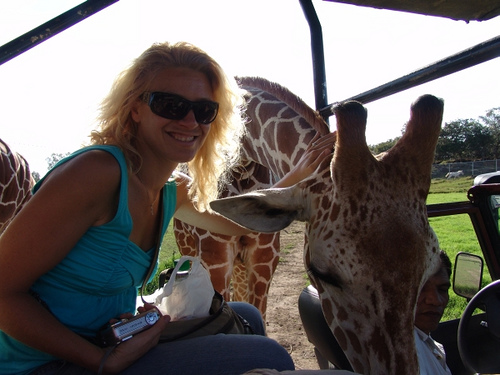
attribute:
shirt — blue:
[0, 137, 183, 366]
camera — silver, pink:
[101, 307, 159, 349]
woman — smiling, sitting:
[1, 38, 351, 375]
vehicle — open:
[0, 1, 499, 373]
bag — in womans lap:
[132, 279, 247, 346]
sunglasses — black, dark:
[144, 89, 230, 125]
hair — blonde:
[92, 37, 257, 222]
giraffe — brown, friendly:
[169, 69, 457, 375]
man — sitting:
[399, 245, 466, 375]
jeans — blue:
[106, 296, 299, 374]